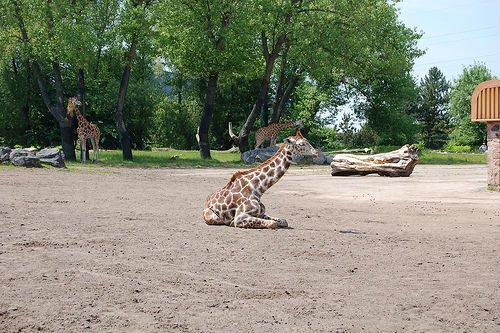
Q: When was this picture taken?
A: Daytime.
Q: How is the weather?
A: Sunny.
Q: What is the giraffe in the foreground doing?
A: Sitting.